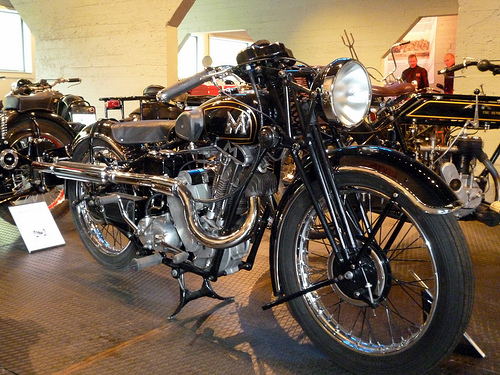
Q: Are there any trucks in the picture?
A: No, there are no trucks.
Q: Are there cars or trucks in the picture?
A: No, there are no trucks or cars.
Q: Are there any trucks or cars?
A: No, there are no trucks or cars.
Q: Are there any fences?
A: No, there are no fences.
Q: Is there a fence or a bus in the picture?
A: No, there are no fences or buses.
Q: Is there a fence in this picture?
A: No, there are no fences.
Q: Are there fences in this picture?
A: No, there are no fences.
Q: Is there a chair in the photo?
A: No, there are no chairs.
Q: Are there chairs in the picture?
A: No, there are no chairs.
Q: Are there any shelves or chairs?
A: No, there are no chairs or shelves.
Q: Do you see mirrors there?
A: No, there are no mirrors.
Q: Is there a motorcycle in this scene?
A: Yes, there are motorcycles.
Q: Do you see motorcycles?
A: Yes, there are motorcycles.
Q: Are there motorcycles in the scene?
A: Yes, there are motorcycles.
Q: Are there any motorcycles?
A: Yes, there are motorcycles.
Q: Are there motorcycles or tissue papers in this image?
A: Yes, there are motorcycles.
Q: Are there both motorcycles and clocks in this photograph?
A: No, there are motorcycles but no clocks.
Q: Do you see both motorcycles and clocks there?
A: No, there are motorcycles but no clocks.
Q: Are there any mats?
A: No, there are no mats.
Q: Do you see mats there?
A: No, there are no mats.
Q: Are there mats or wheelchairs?
A: No, there are no mats or wheelchairs.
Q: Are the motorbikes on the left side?
A: Yes, the motorbikes are on the left of the image.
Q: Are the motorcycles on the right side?
A: No, the motorcycles are on the left of the image.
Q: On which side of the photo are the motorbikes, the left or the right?
A: The motorbikes are on the left of the image.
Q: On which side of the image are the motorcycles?
A: The motorcycles are on the left of the image.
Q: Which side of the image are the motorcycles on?
A: The motorcycles are on the left of the image.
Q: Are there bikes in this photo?
A: Yes, there is a bike.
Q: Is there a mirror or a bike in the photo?
A: Yes, there is a bike.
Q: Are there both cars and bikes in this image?
A: No, there is a bike but no cars.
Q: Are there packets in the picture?
A: No, there are no packets.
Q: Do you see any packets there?
A: No, there are no packets.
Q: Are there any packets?
A: No, there are no packets.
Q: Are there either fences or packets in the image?
A: No, there are no packets or fences.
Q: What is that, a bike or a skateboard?
A: That is a bike.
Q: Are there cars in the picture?
A: No, there are no cars.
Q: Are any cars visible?
A: No, there are no cars.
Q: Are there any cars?
A: No, there are no cars.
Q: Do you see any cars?
A: No, there are no cars.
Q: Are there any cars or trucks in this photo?
A: No, there are no cars or trucks.